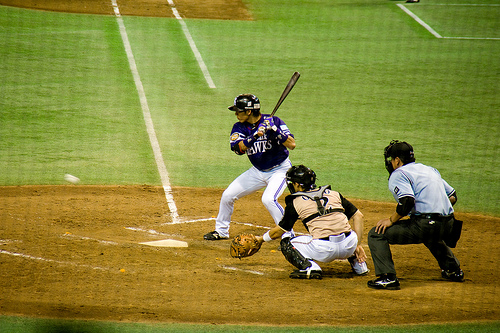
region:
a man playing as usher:
[320, 85, 456, 255]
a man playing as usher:
[337, 213, 387, 305]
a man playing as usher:
[365, 100, 430, 295]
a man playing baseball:
[298, 159, 351, 254]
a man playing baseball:
[268, 188, 315, 309]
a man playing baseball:
[287, 155, 329, 318]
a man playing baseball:
[288, 230, 330, 326]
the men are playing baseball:
[239, 126, 430, 331]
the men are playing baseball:
[217, 105, 345, 310]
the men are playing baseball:
[261, 194, 341, 331]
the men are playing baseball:
[335, 192, 411, 324]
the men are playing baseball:
[263, 52, 371, 282]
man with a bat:
[191, 44, 311, 187]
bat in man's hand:
[258, 60, 312, 117]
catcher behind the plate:
[243, 155, 358, 251]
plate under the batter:
[140, 218, 192, 279]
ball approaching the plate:
[38, 139, 125, 224]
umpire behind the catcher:
[375, 113, 463, 242]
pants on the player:
[201, 165, 286, 225]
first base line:
[111, 101, 196, 172]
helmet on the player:
[213, 86, 258, 134]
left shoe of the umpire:
[358, 260, 402, 313]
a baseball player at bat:
[211, 65, 312, 247]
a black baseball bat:
[253, 68, 302, 138]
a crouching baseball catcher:
[223, 161, 366, 281]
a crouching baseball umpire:
[357, 131, 466, 293]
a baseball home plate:
[135, 233, 188, 248]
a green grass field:
[9, 5, 499, 207]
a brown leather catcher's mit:
[226, 230, 263, 262]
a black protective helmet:
[224, 90, 260, 112]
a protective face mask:
[381, 140, 401, 173]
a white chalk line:
[99, 2, 187, 230]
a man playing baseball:
[216, 86, 318, 306]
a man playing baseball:
[248, 122, 378, 319]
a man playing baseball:
[248, 107, 348, 254]